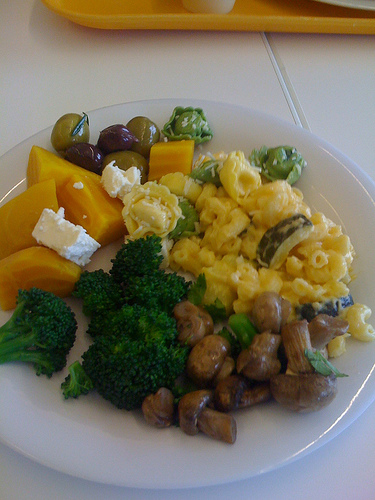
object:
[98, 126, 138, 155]
olive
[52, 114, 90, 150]
olive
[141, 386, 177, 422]
mushrooms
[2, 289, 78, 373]
broccoli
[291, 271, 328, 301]
macaroni and cheese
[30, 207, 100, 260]
feta cheese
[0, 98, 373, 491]
plate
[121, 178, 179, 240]
winter squash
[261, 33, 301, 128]
caulk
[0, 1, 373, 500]
table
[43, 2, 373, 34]
tray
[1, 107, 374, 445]
food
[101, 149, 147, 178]
olives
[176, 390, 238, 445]
mushroom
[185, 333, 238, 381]
mushroom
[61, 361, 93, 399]
broccoli floret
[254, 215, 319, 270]
vegetable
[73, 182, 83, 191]
crumb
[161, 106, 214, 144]
pasta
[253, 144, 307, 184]
pasta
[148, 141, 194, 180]
chunk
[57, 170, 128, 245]
chunk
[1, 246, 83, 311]
chunk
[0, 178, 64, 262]
chunk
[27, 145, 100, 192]
chunk